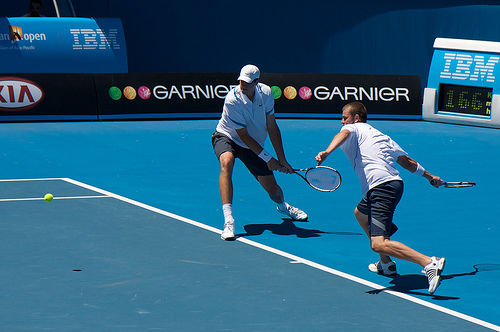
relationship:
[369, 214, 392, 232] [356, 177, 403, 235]
stripe on shorts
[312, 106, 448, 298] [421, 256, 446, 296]
man wearing shoe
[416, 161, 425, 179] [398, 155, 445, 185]
band on arm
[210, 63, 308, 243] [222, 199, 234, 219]
man wearing socks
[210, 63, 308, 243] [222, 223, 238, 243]
man wearing sneakers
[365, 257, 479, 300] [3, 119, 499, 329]
shadow on court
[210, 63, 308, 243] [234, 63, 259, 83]
man wearing hat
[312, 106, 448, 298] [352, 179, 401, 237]
man wearing shorts